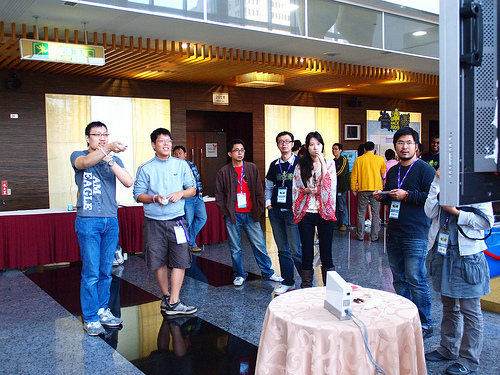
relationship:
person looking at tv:
[374, 129, 441, 358] [440, 0, 500, 208]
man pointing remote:
[71, 121, 133, 336] [118, 143, 131, 150]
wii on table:
[323, 269, 353, 319] [256, 285, 427, 374]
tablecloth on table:
[352, 285, 426, 374] [256, 285, 427, 374]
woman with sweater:
[292, 132, 338, 288] [292, 154, 337, 222]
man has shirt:
[71, 121, 133, 336] [71, 151, 125, 218]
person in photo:
[374, 129, 441, 358] [0, 0, 499, 374]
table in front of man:
[256, 285, 427, 374] [71, 121, 133, 336]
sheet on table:
[352, 290, 376, 312] [256, 285, 427, 374]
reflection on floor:
[53, 301, 164, 373] [0, 241, 282, 374]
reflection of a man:
[81, 324, 117, 374] [71, 121, 133, 336]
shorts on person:
[142, 214, 191, 271] [133, 129, 199, 315]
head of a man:
[85, 121, 107, 150] [71, 121, 133, 336]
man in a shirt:
[214, 143, 283, 288] [234, 167, 253, 212]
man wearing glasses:
[71, 121, 133, 336] [85, 132, 111, 139]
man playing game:
[71, 121, 133, 336] [117, 141, 131, 151]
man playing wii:
[71, 121, 133, 336] [323, 269, 353, 319]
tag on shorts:
[174, 225, 187, 244] [142, 214, 191, 271]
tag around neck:
[277, 187, 289, 203] [281, 151, 293, 160]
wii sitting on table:
[323, 269, 353, 319] [256, 285, 427, 374]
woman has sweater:
[292, 132, 338, 288] [292, 154, 337, 222]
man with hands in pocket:
[214, 143, 283, 288] [222, 210, 264, 225]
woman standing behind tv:
[424, 166, 495, 374] [440, 0, 500, 208]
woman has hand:
[292, 132, 338, 288] [315, 151, 327, 162]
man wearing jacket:
[214, 143, 283, 288] [214, 162, 263, 224]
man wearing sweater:
[263, 132, 300, 295] [266, 153, 298, 209]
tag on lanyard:
[277, 187, 289, 203] [278, 151, 295, 187]